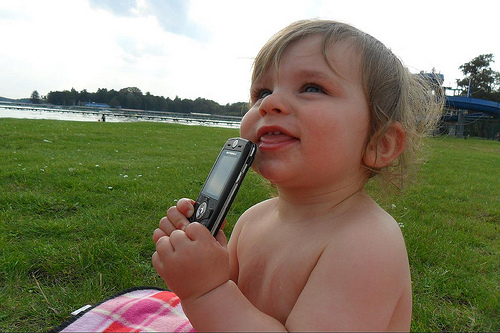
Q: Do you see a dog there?
A: No, there are no dogs.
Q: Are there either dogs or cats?
A: No, there are no dogs or cats.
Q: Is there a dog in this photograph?
A: No, there are no dogs.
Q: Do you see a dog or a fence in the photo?
A: No, there are no dogs or fences.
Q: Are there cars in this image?
A: No, there are no cars.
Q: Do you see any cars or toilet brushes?
A: No, there are no cars or toilet brushes.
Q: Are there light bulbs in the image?
A: No, there are no light bulbs.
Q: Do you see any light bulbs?
A: No, there are no light bulbs.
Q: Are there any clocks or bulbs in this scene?
A: No, there are no bulbs or clocks.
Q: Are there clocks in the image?
A: No, there are no clocks.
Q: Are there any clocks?
A: No, there are no clocks.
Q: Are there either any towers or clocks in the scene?
A: No, there are no clocks or towers.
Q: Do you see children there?
A: Yes, there is a child.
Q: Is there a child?
A: Yes, there is a child.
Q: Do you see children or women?
A: Yes, there is a child.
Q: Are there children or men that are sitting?
A: Yes, the child is sitting.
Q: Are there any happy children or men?
A: Yes, there is a happy child.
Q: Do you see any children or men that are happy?
A: Yes, the child is happy.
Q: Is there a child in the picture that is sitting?
A: Yes, there is a child that is sitting.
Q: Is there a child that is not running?
A: Yes, there is a child that is sitting.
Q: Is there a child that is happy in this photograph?
A: Yes, there is a happy child.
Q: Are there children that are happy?
A: Yes, there is a child that is happy.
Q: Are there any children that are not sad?
A: Yes, there is a happy child.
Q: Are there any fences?
A: No, there are no fences.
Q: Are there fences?
A: No, there are no fences.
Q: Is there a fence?
A: No, there are no fences.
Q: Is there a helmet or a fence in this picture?
A: No, there are no fences or helmets.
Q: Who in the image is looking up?
A: The kid is looking up.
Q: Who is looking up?
A: The kid is looking up.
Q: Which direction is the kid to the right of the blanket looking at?
A: The kid is looking up.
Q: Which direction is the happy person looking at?
A: The kid is looking up.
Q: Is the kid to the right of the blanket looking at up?
A: Yes, the kid is looking up.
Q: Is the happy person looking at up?
A: Yes, the kid is looking up.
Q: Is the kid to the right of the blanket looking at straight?
A: No, the kid is looking up.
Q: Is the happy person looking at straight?
A: No, the kid is looking up.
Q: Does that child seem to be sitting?
A: Yes, the child is sitting.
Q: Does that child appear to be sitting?
A: Yes, the child is sitting.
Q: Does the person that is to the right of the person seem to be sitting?
A: Yes, the child is sitting.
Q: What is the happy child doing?
A: The kid is sitting.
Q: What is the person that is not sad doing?
A: The kid is sitting.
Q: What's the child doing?
A: The kid is sitting.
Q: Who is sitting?
A: The kid is sitting.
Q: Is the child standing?
A: No, the child is sitting.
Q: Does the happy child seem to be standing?
A: No, the child is sitting.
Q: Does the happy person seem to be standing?
A: No, the child is sitting.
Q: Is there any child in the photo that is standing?
A: No, there is a child but he is sitting.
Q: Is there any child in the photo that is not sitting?
A: No, there is a child but he is sitting.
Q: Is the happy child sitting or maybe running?
A: The kid is sitting.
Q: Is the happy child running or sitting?
A: The kid is sitting.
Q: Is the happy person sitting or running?
A: The kid is sitting.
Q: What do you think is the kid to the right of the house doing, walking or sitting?
A: The child is sitting.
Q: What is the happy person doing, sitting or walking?
A: The child is sitting.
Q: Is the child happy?
A: Yes, the child is happy.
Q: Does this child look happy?
A: Yes, the child is happy.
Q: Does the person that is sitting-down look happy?
A: Yes, the child is happy.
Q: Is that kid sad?
A: No, the kid is happy.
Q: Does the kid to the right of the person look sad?
A: No, the child is happy.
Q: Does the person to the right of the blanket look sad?
A: No, the child is happy.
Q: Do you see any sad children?
A: No, there is a child but he is happy.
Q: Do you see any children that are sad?
A: No, there is a child but he is happy.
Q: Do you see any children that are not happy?
A: No, there is a child but he is happy.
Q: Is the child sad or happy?
A: The child is happy.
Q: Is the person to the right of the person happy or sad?
A: The child is happy.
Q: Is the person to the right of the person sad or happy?
A: The child is happy.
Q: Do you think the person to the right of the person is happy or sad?
A: The child is happy.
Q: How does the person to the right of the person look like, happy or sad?
A: The child is happy.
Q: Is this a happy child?
A: Yes, this is a happy child.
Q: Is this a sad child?
A: No, this is a happy child.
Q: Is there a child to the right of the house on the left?
A: Yes, there is a child to the right of the house.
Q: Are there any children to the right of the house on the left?
A: Yes, there is a child to the right of the house.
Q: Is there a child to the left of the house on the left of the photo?
A: No, the child is to the right of the house.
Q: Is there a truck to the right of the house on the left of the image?
A: No, there is a child to the right of the house.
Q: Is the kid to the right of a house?
A: Yes, the kid is to the right of a house.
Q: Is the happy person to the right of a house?
A: Yes, the kid is to the right of a house.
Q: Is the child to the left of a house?
A: No, the child is to the right of a house.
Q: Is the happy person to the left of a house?
A: No, the child is to the right of a house.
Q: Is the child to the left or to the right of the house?
A: The child is to the right of the house.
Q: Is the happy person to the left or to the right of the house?
A: The child is to the right of the house.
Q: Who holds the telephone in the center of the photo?
A: The kid holds the phone.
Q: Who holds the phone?
A: The kid holds the phone.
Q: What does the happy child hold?
A: The child holds the phone.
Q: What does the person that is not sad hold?
A: The child holds the phone.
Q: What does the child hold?
A: The child holds the phone.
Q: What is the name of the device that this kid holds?
A: The device is a phone.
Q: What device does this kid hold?
A: The kid holds the phone.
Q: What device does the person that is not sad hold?
A: The kid holds the phone.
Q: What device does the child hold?
A: The kid holds the phone.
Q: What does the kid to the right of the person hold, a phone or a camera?
A: The kid holds a phone.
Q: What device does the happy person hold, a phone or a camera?
A: The kid holds a phone.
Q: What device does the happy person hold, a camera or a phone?
A: The kid holds a phone.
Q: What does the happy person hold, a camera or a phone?
A: The kid holds a phone.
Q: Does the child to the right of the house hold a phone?
A: Yes, the child holds a phone.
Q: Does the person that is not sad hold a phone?
A: Yes, the child holds a phone.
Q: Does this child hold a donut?
A: No, the child holds a phone.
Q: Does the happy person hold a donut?
A: No, the child holds a phone.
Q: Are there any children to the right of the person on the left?
A: Yes, there is a child to the right of the person.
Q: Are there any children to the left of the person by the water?
A: No, the child is to the right of the person.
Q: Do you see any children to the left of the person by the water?
A: No, the child is to the right of the person.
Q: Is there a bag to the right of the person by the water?
A: No, there is a child to the right of the person.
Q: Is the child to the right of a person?
A: Yes, the child is to the right of a person.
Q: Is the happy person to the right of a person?
A: Yes, the child is to the right of a person.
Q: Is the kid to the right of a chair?
A: No, the kid is to the right of a person.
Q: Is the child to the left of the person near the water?
A: No, the child is to the right of the person.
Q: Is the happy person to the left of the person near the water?
A: No, the child is to the right of the person.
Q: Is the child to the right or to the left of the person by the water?
A: The child is to the right of the person.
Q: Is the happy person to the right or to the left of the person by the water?
A: The child is to the right of the person.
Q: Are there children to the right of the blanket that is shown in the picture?
A: Yes, there is a child to the right of the blanket.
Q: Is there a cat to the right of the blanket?
A: No, there is a child to the right of the blanket.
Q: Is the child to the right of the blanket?
A: Yes, the child is to the right of the blanket.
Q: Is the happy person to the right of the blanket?
A: Yes, the child is to the right of the blanket.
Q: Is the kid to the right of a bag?
A: No, the kid is to the right of the blanket.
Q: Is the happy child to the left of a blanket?
A: No, the child is to the right of a blanket.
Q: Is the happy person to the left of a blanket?
A: No, the child is to the right of a blanket.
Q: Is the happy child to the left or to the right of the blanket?
A: The child is to the right of the blanket.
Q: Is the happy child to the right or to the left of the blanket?
A: The child is to the right of the blanket.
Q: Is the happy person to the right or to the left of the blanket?
A: The child is to the right of the blanket.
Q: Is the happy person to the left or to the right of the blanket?
A: The child is to the right of the blanket.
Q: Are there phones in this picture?
A: Yes, there is a phone.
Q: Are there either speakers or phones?
A: Yes, there is a phone.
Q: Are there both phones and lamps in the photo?
A: No, there is a phone but no lamps.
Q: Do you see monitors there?
A: No, there are no monitors.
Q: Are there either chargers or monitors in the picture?
A: No, there are no monitors or chargers.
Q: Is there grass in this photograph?
A: Yes, there is grass.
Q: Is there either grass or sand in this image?
A: Yes, there is grass.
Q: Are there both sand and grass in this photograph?
A: No, there is grass but no sand.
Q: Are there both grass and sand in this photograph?
A: No, there is grass but no sand.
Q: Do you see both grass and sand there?
A: No, there is grass but no sand.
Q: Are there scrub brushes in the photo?
A: No, there are no scrub brushes.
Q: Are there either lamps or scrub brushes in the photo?
A: No, there are no scrub brushes or lamps.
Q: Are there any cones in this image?
A: No, there are no cones.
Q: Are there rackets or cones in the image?
A: No, there are no cones or rackets.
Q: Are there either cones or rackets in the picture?
A: No, there are no cones or rackets.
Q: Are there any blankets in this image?
A: Yes, there is a blanket.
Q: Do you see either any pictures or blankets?
A: Yes, there is a blanket.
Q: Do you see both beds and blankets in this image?
A: No, there is a blanket but no beds.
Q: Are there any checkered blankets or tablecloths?
A: Yes, there is a checkered blanket.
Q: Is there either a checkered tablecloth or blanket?
A: Yes, there is a checkered blanket.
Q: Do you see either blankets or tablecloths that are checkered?
A: Yes, the blanket is checkered.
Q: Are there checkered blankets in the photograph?
A: Yes, there is a checkered blanket.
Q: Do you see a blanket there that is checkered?
A: Yes, there is a blanket that is checkered.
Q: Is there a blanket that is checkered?
A: Yes, there is a blanket that is checkered.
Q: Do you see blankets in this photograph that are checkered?
A: Yes, there is a blanket that is checkered.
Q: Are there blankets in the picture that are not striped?
A: Yes, there is a checkered blanket.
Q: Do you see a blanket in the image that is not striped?
A: Yes, there is a checkered blanket.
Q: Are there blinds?
A: No, there are no blinds.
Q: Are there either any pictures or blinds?
A: No, there are no blinds or pictures.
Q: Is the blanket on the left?
A: Yes, the blanket is on the left of the image.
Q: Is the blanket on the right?
A: No, the blanket is on the left of the image.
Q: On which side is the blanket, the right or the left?
A: The blanket is on the left of the image.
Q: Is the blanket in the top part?
A: No, the blanket is in the bottom of the image.